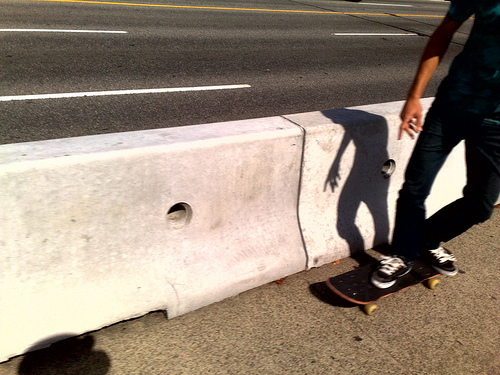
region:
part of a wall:
[242, 150, 269, 221]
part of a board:
[345, 288, 347, 295]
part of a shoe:
[386, 272, 392, 280]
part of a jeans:
[412, 215, 414, 221]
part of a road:
[154, 77, 164, 84]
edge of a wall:
[160, 130, 169, 145]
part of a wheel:
[358, 308, 375, 328]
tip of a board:
[361, 278, 381, 298]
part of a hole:
[172, 206, 192, 233]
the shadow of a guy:
[314, 103, 392, 258]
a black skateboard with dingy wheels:
[316, 255, 463, 315]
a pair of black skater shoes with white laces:
[371, 244, 458, 288]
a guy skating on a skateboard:
[323, 1, 498, 315]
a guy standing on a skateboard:
[320, 0, 498, 315]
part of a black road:
[2, 0, 434, 140]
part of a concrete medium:
[0, 99, 410, 362]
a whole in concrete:
[166, 202, 194, 229]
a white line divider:
[329, 28, 418, 39]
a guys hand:
[396, 96, 426, 142]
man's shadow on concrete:
[271, 40, 390, 217]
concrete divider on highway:
[1, 91, 476, 268]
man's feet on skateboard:
[372, 185, 492, 281]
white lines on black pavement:
[14, 61, 255, 136]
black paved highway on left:
[22, 6, 497, 118]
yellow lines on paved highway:
[18, 3, 496, 17]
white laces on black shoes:
[383, 240, 426, 285]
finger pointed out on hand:
[394, 115, 435, 160]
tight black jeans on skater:
[370, 113, 495, 259]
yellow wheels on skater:
[360, 303, 387, 322]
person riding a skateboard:
[317, 235, 471, 315]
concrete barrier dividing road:
[2, 138, 304, 305]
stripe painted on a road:
[4, 75, 264, 104]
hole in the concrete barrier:
[155, 202, 198, 237]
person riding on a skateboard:
[337, 2, 488, 317]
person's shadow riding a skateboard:
[306, 100, 396, 272]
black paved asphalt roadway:
[12, 0, 382, 88]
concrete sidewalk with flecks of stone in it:
[255, 315, 351, 360]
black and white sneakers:
[368, 252, 409, 292]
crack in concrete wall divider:
[272, 115, 322, 270]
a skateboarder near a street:
[32, 12, 477, 332]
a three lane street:
[8, 3, 423, 143]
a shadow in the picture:
[9, 313, 129, 371]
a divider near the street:
[9, 101, 462, 283]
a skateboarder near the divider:
[357, 23, 490, 294]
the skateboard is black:
[313, 225, 493, 314]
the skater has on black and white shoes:
[365, 246, 465, 291]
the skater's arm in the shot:
[393, 44, 451, 150]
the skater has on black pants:
[354, 33, 482, 290]